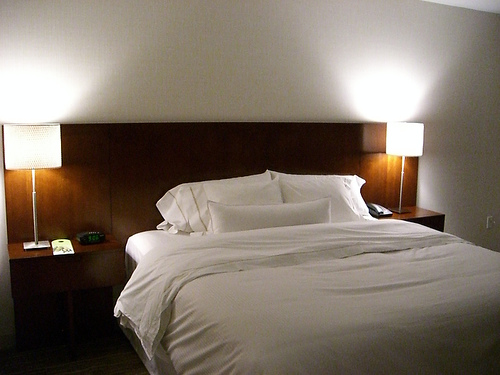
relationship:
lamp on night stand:
[1, 110, 58, 267] [6, 234, 106, 372]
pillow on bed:
[221, 199, 363, 240] [186, 204, 461, 368]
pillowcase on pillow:
[161, 174, 285, 240] [156, 170, 273, 240]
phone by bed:
[367, 194, 387, 221] [117, 174, 499, 374]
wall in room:
[0, 1, 498, 254] [5, 5, 496, 372]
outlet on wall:
[484, 214, 495, 231] [4, 7, 495, 234]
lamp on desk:
[1, 110, 58, 267] [7, 232, 124, 361]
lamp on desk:
[385, 121, 425, 213] [366, 206, 443, 233]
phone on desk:
[367, 194, 387, 221] [369, 206, 446, 233]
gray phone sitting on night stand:
[362, 194, 394, 223] [367, 191, 448, 235]